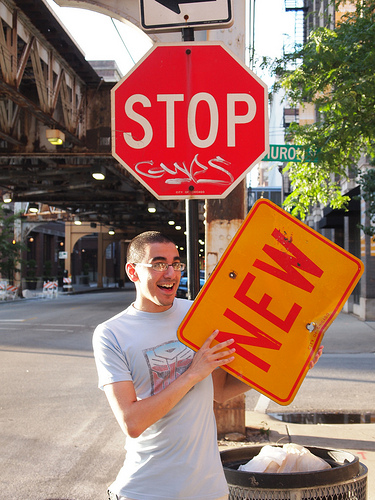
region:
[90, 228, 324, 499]
A young man standing in front of a stop sign.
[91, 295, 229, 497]
The young man is wearing a worn out shirt.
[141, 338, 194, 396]
The logo of the Transformer movie.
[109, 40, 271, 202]
A gigantic stop sign in the street.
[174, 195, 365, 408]
A sign that has NEW written on it.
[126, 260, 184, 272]
The young man is wearing a pair of glasses.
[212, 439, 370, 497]
A public garbage can made of metal.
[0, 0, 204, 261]
A bridge made for trains to cross.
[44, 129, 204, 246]
Some lights are under the bridge.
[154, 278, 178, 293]
The young man has a beautiful smile.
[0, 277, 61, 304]
Barricades for the road.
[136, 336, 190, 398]
The transformers symbol.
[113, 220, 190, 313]
The man is smiling.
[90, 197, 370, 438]
The man is holding a sign.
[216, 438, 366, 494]
A garbage bin.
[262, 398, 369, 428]
A puddle of water.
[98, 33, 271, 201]
A stop sign.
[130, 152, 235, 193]
Graffiti on the stop sign.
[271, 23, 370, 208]
Leaves and branches of a tree.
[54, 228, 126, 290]
Support beams.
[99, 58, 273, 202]
The sign is red and white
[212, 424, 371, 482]
There is garbage behind the man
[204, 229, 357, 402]
The sign says new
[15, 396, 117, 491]
The road is gray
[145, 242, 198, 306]
The man has glasses on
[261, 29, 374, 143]
The trees are tall and green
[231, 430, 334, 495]
The garbage can is black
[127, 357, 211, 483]
The man has an off white shirt on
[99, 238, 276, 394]
The man is holding a sign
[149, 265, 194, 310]
The man is smiling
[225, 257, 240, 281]
stud in the yellow sign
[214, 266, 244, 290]
small hole in yellow sign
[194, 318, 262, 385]
man's sign holding sign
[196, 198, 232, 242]
brown rust on white post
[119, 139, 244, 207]
grafitti on red sign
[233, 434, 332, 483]
white trash in trash can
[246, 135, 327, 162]
large green and white sign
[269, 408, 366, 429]
small puddle of water on sidewald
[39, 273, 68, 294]
orange and white emergency barriers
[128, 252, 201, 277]
wire rimmed glasses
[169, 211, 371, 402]
orange sign says NEW in red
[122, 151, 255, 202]
graffiti on the stop sign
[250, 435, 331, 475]
trash in the trash can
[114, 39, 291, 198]
STOP sign is red and white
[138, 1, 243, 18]
black arrow pointing left on sign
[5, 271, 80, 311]
hazard stands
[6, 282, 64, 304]
hazard signs have orange stripes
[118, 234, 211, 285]
man wearing glasses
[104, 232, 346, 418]
man holding orange sign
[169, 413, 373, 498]
man standing next to trash can